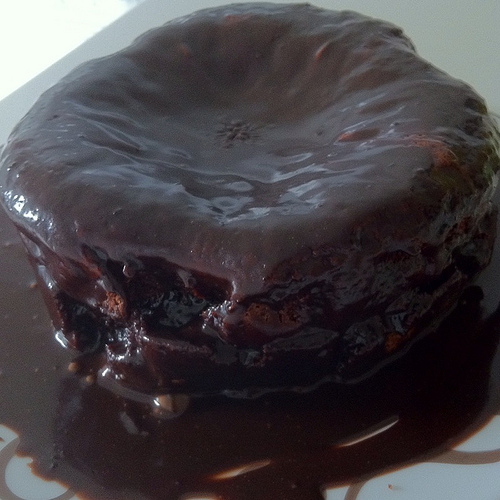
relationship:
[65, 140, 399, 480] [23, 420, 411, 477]
chocolate on plate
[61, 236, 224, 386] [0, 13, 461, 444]
dip in cake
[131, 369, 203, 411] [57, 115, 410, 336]
bubble in chocolate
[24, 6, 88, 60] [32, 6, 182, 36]
white in background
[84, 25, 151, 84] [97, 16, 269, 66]
shadow being cast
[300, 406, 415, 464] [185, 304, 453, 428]
white in chocolate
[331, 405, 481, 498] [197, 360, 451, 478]
line on plate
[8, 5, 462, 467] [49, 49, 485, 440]
dessert shaped like a cupcake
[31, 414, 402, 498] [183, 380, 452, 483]
sauce on plate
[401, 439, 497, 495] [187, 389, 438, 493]
corner of plate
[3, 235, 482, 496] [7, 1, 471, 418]
chocolate syrup surrounding desert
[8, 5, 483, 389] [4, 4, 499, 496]
chocolate dessert on a plate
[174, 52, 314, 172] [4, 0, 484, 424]
dip in middle of food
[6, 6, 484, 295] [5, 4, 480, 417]
chocolate frosting covering dessert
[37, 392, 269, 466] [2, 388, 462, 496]
dessert sauce spilled to plate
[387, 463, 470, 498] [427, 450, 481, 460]
white plate with a brown/decorative line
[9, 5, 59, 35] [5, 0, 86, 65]
light source in left corner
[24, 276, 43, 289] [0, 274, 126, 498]
bubble in chocolate sauce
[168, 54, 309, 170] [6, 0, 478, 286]
dip on top of chocolate/cake top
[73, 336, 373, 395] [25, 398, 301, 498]
chocolate/cake bottom on chocolate sauce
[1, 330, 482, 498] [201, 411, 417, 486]
sauce in plate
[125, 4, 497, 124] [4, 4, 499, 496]
corner in plate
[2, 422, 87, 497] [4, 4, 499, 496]
circle in plate